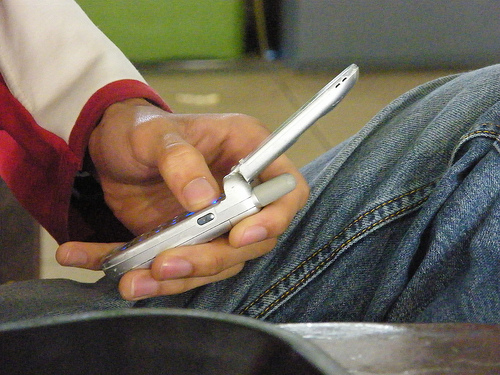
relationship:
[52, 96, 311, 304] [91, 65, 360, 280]
hand holding cell phone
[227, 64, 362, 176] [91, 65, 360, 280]
top of cell phone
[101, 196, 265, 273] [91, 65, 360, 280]
side of phone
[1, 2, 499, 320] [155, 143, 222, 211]
person has thumb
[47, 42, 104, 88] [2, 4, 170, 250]
part of sleeve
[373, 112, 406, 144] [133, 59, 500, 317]
part of jeans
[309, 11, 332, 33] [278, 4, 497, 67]
part of wall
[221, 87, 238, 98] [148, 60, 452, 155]
part of ground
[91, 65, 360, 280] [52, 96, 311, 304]
cell phone in hand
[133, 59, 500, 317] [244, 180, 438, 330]
jeans have hem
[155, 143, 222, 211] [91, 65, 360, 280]
thumb on cell phone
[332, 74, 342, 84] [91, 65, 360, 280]
tiny opening at top of cell phoe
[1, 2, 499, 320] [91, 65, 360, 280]
person holding cell phone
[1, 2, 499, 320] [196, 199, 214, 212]
person pushig butto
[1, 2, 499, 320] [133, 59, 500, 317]
person wearing jeas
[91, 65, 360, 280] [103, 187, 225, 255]
cell phone has light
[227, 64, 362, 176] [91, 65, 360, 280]
top of phoe